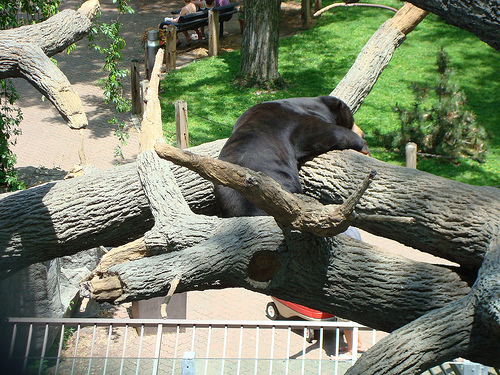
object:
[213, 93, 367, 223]
animal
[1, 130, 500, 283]
branch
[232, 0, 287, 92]
tree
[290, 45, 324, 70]
grass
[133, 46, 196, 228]
limb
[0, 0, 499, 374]
tree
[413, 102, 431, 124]
leaves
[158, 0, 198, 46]
person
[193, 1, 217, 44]
person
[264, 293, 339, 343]
wagon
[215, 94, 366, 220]
fur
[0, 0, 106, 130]
tree branch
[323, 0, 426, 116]
tree branch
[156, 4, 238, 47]
bench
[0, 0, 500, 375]
zoo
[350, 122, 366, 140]
nose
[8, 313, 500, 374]
fence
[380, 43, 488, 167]
bush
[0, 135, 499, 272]
tree branch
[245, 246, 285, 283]
hole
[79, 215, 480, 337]
tree trunk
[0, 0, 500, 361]
ground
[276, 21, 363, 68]
patch